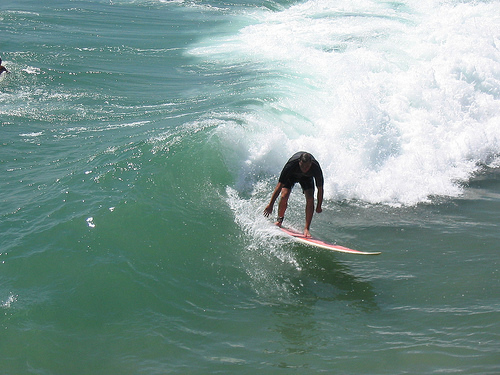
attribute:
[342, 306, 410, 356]
ripples — small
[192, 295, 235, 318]
ripples — small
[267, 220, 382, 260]
surfboard — red and white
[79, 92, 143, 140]
ripples — small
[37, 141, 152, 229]
ripples — small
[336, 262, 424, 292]
ripples — small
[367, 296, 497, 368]
ripples — small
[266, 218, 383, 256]
surfboard — red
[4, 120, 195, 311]
ripples — small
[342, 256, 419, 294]
ripples — small